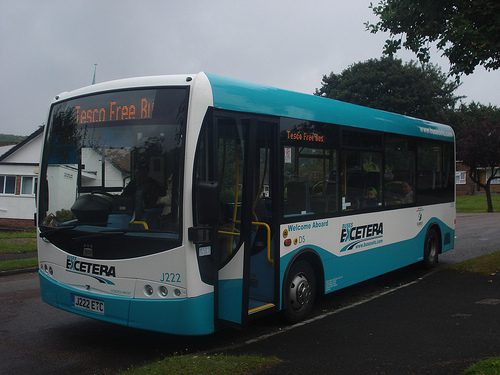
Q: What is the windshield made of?
A: Glass.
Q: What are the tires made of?
A: Rubber.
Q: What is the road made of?
A: Asphalt.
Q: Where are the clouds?
A: In the sky.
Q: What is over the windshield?
A: The display screen.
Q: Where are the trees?
A: Behind the bus.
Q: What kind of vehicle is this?
A: A bus.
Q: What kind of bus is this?
A: A charter bus.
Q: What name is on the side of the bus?
A: Etcetera.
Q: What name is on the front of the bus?
A: Etcetera.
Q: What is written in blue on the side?
A: Welcome aboard.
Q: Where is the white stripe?
A: The middle of the bus.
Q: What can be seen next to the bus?
A: A White House.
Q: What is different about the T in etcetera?
A: It's blue.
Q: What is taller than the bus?
A: Trees in the background.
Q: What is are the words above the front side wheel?
A: Welcome Aboard.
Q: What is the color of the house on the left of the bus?
A: White.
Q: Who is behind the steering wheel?
A: The driver.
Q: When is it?
A: Daytime.